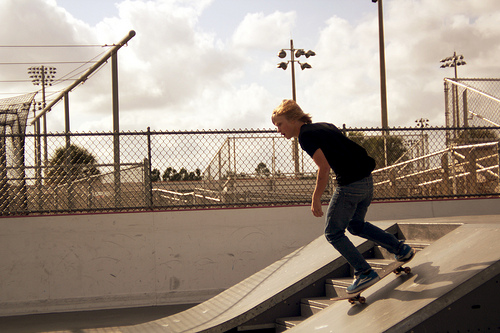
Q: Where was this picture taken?
A: Skateboard park.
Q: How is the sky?
A: Cloudy.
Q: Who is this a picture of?
A: A skateboarder.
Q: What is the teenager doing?
A: Skateboarding.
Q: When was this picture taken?
A: Daytime.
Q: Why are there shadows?
A: From the sun.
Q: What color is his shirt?
A: Black.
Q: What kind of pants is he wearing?
A: Jeans.